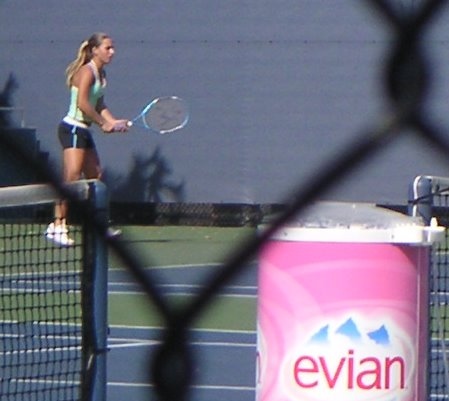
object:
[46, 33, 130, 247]
person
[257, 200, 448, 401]
container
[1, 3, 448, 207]
wall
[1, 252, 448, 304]
court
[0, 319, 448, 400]
court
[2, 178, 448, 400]
nets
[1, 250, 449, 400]
courts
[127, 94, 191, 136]
racket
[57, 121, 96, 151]
shorts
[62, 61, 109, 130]
green shirt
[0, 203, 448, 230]
black bottom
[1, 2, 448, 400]
fence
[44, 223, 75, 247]
shoe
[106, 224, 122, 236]
shoe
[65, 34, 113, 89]
long hair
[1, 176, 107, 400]
net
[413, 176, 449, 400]
net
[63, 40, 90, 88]
ponytail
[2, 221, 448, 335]
surround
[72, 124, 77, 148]
stripe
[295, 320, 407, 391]
logo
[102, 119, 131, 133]
hands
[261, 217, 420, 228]
water bottles